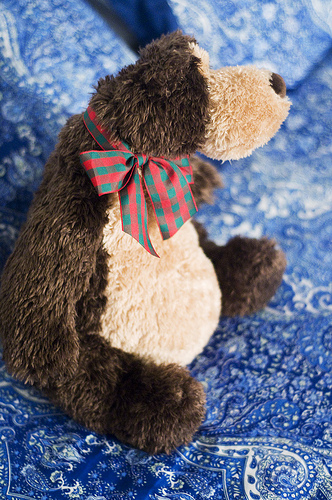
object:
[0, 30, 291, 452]
teddy bear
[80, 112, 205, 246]
bow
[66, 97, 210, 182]
neck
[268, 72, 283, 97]
nose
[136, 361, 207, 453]
right foot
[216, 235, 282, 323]
left foot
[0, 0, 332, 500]
bedspread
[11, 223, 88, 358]
right arm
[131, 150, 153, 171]
knot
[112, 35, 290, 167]
head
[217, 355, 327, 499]
design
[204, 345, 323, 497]
paisley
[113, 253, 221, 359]
tummy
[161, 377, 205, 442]
paw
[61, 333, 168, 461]
leg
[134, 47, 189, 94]
ear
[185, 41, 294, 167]
face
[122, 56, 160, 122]
fur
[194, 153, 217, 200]
left arm